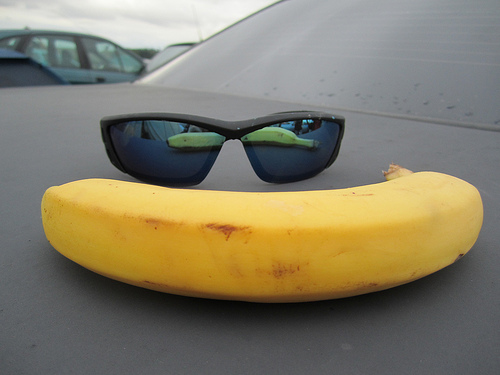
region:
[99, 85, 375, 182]
Pair of sunglasses.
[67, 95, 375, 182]
Sunglasses are black.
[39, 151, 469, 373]
One banana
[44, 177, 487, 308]
The banana is yellow.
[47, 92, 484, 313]
Sunglasses and a banana on a car.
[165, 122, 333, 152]
reflection of a banana in the sunglasses.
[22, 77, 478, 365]
The car is black.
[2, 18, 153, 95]
Blue sedan in the background.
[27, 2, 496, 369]
Photo taken during the day.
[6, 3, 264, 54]
Clouds in the sky.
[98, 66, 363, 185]
glasses on a surface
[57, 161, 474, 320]
yellow banana in front of sunglasses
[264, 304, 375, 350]
black surface underneath banana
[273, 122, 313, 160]
banana in reflection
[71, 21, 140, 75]
car window in background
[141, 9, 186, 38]
clouds in the sky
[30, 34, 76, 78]
window on the car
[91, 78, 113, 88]
door of the car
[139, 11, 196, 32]
sky in the background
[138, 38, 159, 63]
trees behind the cars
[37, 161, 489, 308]
yellow banana in foreground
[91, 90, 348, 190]
black sunglasses behind banana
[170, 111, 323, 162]
banana reflected in sunglasses lenses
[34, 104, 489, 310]
banana and sunglasses on roof of car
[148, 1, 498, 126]
dirty car window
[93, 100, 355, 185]
black sunglasses with blue-tinted lenses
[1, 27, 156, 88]
blue car in background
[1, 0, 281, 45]
cloudy sky in background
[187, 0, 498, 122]
white horizontal lines on car window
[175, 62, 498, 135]
small dots at bottom of window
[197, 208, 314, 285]
Brown spots on banana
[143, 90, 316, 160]
Reflection on sunglasses of banana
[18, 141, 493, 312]
Yellow banana on car hood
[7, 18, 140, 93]
Blue car in background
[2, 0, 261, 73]
Dark and cloudy sky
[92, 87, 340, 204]
Black sunglasses on hood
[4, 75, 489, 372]
Black hood of car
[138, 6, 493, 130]
Black car window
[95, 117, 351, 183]
Reflective sun glass lenses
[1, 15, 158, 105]
Two cars in background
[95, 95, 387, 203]
The sunglasses are black.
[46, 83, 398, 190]
The sunglasses are sitting on the ground.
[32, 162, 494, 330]
The banana is sitting on the ground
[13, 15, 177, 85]
The car is parked.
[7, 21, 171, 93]
The car is grey.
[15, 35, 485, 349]
They are sitting on the car.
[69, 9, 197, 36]
It is a cloudy day outside.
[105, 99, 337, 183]
the reflection of the banana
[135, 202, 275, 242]
a brown spot on the banana